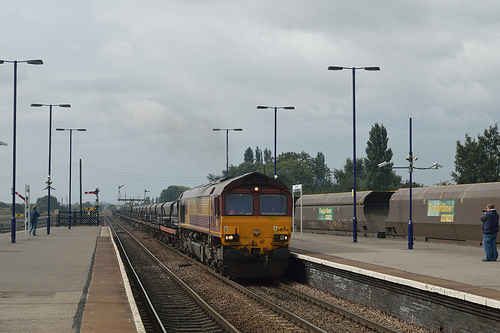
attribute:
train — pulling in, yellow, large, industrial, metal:
[111, 170, 294, 281]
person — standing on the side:
[28, 204, 40, 237]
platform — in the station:
[1, 224, 146, 332]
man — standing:
[481, 202, 499, 261]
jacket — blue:
[480, 209, 500, 233]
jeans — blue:
[483, 230, 500, 260]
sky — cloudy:
[1, 0, 500, 204]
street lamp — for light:
[30, 100, 70, 235]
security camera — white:
[377, 158, 389, 170]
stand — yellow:
[83, 206, 99, 226]